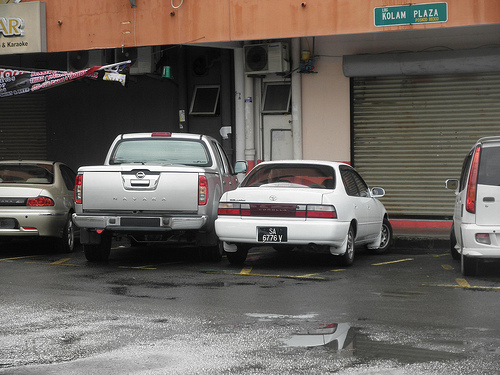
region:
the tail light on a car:
[208, 184, 343, 253]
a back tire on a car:
[315, 225, 367, 271]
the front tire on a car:
[356, 203, 427, 260]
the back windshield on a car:
[234, 142, 343, 201]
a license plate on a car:
[234, 217, 316, 271]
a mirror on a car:
[362, 180, 389, 215]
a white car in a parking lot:
[211, 140, 405, 268]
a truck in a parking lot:
[51, 100, 262, 256]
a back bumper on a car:
[206, 206, 391, 268]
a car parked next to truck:
[58, 109, 440, 299]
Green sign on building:
[373, 1, 448, 31]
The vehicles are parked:
[0, 122, 495, 269]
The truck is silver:
[73, 122, 230, 247]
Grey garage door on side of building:
[341, 51, 496, 213]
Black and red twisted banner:
[3, 55, 130, 98]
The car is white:
[218, 147, 393, 273]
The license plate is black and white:
[256, 228, 292, 244]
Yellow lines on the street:
[15, 228, 490, 299]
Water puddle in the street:
[276, 320, 466, 367]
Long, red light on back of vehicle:
[450, 137, 493, 231]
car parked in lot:
[21, 153, 66, 221]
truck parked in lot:
[70, 120, 211, 220]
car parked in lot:
[215, 146, 370, 267]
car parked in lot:
[433, 136, 498, 271]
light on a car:
[285, 195, 346, 233]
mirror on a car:
[362, 183, 385, 211]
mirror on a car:
[426, 176, 461, 196]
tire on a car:
[337, 220, 358, 262]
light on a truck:
[187, 175, 217, 202]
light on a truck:
[67, 173, 101, 208]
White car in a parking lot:
[218, 122, 394, 286]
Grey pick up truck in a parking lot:
[69, 76, 237, 258]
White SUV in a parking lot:
[421, 90, 498, 305]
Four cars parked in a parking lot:
[1, 74, 498, 313]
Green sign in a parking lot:
[301, 0, 453, 318]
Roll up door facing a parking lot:
[315, 51, 499, 270]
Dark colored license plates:
[250, 212, 305, 249]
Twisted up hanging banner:
[0, 44, 162, 116]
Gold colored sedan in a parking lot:
[0, 120, 78, 279]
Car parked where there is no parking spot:
[201, 131, 444, 301]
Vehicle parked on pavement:
[434, 123, 493, 285]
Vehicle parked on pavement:
[221, 141, 386, 288]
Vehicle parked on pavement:
[90, 120, 238, 268]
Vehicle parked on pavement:
[5, 125, 92, 287]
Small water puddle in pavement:
[306, 315, 366, 360]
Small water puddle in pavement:
[370, 325, 405, 371]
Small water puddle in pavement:
[418, 325, 474, 372]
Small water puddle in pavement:
[245, 303, 320, 331]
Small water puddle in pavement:
[370, 280, 412, 315]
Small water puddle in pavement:
[75, 263, 280, 314]